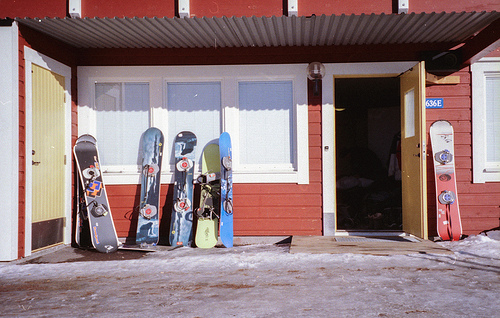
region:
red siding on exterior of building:
[235, 187, 321, 232]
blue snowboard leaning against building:
[215, 128, 237, 250]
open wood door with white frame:
[317, 51, 432, 243]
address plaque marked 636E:
[423, 93, 445, 109]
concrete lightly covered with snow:
[188, 262, 434, 312]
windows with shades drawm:
[232, 65, 303, 175]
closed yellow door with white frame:
[23, 60, 76, 255]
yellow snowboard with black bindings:
[192, 136, 218, 254]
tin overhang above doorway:
[10, 12, 492, 48]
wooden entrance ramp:
[282, 225, 449, 260]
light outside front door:
[300, 43, 330, 99]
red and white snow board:
[420, 114, 480, 246]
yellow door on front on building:
[29, 57, 77, 252]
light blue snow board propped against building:
[216, 126, 246, 248]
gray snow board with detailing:
[170, 126, 199, 254]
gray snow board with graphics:
[69, 126, 129, 264]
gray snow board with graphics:
[127, 116, 167, 247]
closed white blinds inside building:
[75, 57, 330, 197]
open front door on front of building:
[326, 61, 421, 243]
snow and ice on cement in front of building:
[57, 236, 427, 316]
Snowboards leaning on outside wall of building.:
[74, 124, 253, 257]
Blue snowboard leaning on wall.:
[215, 131, 240, 251]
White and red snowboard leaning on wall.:
[425, 116, 482, 255]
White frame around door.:
[322, 58, 425, 250]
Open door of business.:
[399, 60, 429, 244]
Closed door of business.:
[31, 59, 68, 259]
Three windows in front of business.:
[88, 74, 298, 181]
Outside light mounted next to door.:
[303, 58, 327, 100]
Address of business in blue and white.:
[419, 91, 454, 110]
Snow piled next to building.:
[440, 231, 498, 263]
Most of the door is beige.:
[32, 73, 72, 220]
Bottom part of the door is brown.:
[26, 215, 79, 245]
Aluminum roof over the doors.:
[29, 4, 494, 69]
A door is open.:
[316, 63, 428, 245]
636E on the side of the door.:
[426, 90, 451, 112]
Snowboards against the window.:
[71, 130, 254, 255]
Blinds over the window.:
[99, 81, 294, 168]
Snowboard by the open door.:
[429, 115, 479, 245]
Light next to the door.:
[298, 54, 331, 99]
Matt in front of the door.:
[321, 229, 419, 251]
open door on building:
[319, 60, 439, 250]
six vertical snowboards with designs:
[60, 117, 246, 259]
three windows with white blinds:
[76, 61, 311, 186]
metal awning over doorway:
[195, 6, 377, 57]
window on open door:
[391, 80, 424, 151]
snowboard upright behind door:
[419, 111, 466, 251]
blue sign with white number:
[419, 93, 449, 114]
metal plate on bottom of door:
[21, 210, 70, 262]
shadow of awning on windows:
[97, 83, 277, 125]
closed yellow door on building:
[20, 63, 74, 254]